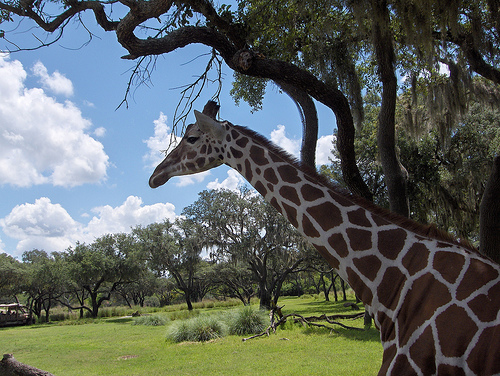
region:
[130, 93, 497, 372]
giraffe on a grassy field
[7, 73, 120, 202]
sky full of clouds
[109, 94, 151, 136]
a clear blue sky with no clouds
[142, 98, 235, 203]
head of a giraffe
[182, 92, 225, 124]
ear of a giraffe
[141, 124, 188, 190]
mouth of a giraffe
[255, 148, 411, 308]
neck of a giraffe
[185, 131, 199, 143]
eyes of a giraffe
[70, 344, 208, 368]
a green grassy field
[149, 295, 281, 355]
bushes on a grassy field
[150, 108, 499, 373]
a giraffe standing in the field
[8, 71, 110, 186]
a white cloud in the sky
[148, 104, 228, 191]
the head of the giraffe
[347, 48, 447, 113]
the sky through the trees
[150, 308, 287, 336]
a bush on the grass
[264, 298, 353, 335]
sticks on the ground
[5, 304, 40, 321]
a car in the distance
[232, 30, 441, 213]
trunks of trees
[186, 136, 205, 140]
the eye of the giraffe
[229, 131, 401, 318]
the neck of the giraffe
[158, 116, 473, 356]
brown giraffe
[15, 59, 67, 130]
white clouds in blue sky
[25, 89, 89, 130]
white clouds in blue sky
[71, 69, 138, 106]
white clouds in blue sky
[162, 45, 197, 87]
white clouds in blue sky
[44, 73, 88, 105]
white clouds in blue sky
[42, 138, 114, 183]
white clouds in blue sky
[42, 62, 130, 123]
white clouds in blue sky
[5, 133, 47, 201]
white clouds in blue sky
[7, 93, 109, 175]
white clouds in blue sky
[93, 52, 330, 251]
the head of a giraffe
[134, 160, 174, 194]
the mouth of a giraffe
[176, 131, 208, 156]
the eye of a giraffe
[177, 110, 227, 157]
the ear of a giraffe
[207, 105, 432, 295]
the neck of a giraffe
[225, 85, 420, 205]
the main of a giraffe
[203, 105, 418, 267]
a long neck on a giraffe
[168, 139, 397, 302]
the brown spots on a giraffe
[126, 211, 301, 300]
green leaves on trees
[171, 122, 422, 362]
a giraffe near a tree